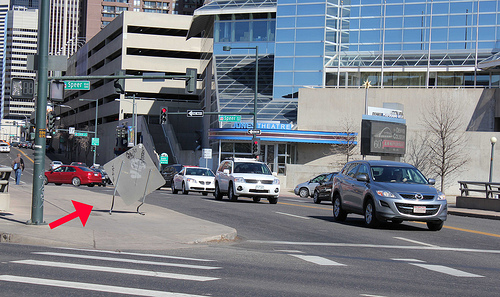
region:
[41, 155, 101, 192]
the car is red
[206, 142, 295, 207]
the SUV is white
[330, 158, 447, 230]
car approaching busy intersection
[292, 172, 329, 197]
car approaching busy intersection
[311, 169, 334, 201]
car approaching busy intersection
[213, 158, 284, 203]
car approaching busy intersection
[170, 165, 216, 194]
car approaching busy intersection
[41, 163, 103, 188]
car approaching busy intersection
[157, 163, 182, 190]
car approaching busy intersection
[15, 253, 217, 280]
white cross walk line in street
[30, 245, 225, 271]
white cross walk line in street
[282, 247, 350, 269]
white cross walk line in street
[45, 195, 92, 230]
a drawn red arrow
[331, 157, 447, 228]
a gray mini van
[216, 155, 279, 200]
a white transportation van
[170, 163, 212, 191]
a small white compact car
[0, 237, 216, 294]
several white stripes on the street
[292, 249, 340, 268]
white paint on the asphalt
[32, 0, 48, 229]
a green metal power pole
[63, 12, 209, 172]
a gray multi leveled building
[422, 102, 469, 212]
a leafless brown tree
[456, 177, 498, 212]
a metal and concrete median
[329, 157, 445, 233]
Large silver metal car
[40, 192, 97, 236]
Large red long arrow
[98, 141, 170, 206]
Large grey diamond metal sign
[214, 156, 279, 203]
Large white metal car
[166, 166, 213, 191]
Small white metal car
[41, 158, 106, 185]
Small red metal car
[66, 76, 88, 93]
Small short green sign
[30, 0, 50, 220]
Large tall metal pole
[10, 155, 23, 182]
Small short blue person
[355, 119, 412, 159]
Small black square sign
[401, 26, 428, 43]
WINDOWS ON THE BUILDING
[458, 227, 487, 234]
YELLOW LINE ON THE STREET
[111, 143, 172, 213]
SIGN POSTED ON SIDEWALK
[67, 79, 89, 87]
STREET SIGN ON THE POLE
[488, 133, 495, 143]
LIGHT ON THE POLE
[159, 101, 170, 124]
TRAFFIC LIGHT ON RED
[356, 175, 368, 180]
MIRROR ON THE CAR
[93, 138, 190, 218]
sign on the sidewalk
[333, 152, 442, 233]
silver car on the street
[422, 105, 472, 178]
small bare tree on sidewalk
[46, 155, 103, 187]
red car turning on the street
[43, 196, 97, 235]
red arrow on the corner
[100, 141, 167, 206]
back of a street sign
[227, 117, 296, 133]
blue sign on a theatre